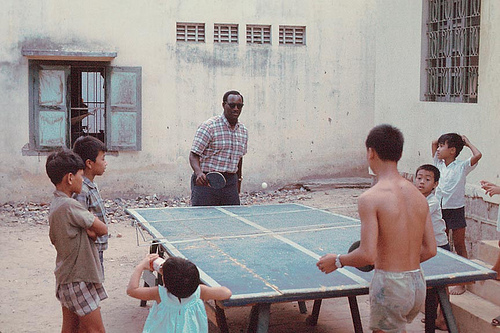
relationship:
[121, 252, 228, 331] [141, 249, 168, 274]
child drinking from cup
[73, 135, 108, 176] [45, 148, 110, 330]
head of boy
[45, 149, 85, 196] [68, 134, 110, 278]
head of boy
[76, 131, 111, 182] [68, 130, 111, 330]
head of child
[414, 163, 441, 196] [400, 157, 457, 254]
head of child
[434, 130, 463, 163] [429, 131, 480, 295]
head of boy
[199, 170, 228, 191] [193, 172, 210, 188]
ping-pong paddle in hand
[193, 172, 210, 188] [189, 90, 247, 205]
hand on man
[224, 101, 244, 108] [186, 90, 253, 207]
sunglasses on man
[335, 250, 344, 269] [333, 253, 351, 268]
silver watch on wrist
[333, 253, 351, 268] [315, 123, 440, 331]
wrist on boy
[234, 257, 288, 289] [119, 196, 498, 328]
paint on table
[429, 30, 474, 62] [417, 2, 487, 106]
bars over window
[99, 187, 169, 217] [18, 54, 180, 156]
rubble overnear window